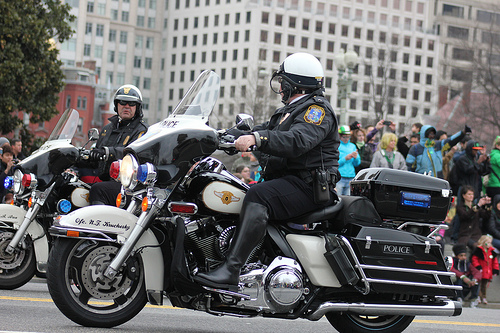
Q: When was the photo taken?
A: Daytime.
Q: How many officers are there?
A: Two.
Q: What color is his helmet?
A: White.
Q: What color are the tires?
A: Black.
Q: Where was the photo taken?
A: On city street.